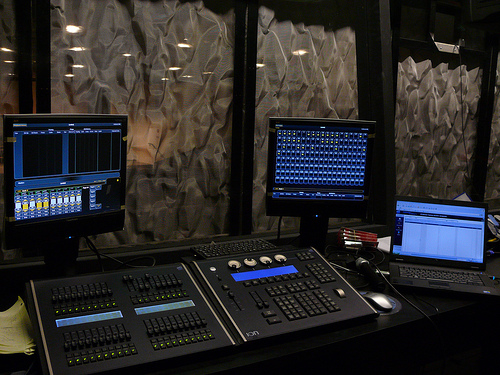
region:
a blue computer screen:
[258, 93, 392, 220]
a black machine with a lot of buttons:
[57, 253, 217, 369]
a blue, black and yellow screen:
[13, 81, 155, 237]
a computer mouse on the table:
[363, 285, 414, 320]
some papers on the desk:
[3, 283, 50, 360]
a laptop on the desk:
[386, 188, 491, 289]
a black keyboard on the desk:
[193, 216, 300, 266]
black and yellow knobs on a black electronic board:
[141, 283, 248, 358]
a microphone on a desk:
[354, 246, 394, 328]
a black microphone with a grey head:
[348, 243, 411, 293]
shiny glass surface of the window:
[126, 25, 218, 207]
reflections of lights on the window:
[3, 14, 290, 91]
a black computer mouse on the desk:
[364, 286, 397, 321]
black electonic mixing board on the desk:
[57, 246, 327, 362]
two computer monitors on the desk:
[3, 99, 388, 244]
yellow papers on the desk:
[0, 300, 47, 364]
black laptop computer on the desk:
[398, 193, 498, 305]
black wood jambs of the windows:
[226, 5, 276, 239]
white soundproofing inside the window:
[411, 59, 467, 184]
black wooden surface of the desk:
[229, 311, 419, 373]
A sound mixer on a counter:
[20, 246, 390, 373]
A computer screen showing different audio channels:
[1, 108, 153, 259]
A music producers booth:
[0, 88, 497, 369]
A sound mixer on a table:
[203, 246, 385, 348]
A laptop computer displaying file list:
[391, 193, 498, 308]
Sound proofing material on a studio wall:
[133, 13, 219, 202]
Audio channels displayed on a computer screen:
[0, 106, 144, 244]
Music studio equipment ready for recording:
[6, 65, 496, 372]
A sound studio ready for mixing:
[4, 96, 499, 373]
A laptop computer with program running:
[386, 190, 497, 325]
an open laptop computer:
[389, 198, 492, 297]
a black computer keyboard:
[397, 262, 482, 284]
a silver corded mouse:
[365, 287, 389, 309]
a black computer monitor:
[267, 120, 374, 217]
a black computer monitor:
[2, 112, 125, 241]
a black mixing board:
[185, 232, 380, 348]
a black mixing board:
[24, 261, 235, 373]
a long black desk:
[3, 207, 492, 372]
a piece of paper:
[2, 295, 36, 356]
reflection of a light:
[173, 40, 190, 49]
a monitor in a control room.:
[378, 180, 498, 282]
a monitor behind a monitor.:
[261, 111, 387, 218]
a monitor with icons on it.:
[0, 99, 159, 259]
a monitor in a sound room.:
[27, 260, 249, 373]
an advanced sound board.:
[186, 232, 377, 366]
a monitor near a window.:
[246, 92, 406, 227]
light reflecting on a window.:
[171, 29, 203, 50]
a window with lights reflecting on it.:
[49, 12, 224, 244]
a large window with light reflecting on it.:
[253, 20, 361, 215]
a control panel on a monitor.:
[0, 78, 155, 276]